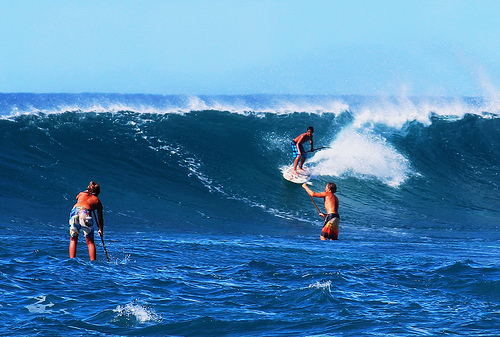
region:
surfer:
[266, 107, 323, 182]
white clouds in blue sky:
[8, 39, 47, 85]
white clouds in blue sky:
[41, 7, 99, 71]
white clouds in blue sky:
[214, 21, 276, 78]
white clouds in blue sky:
[316, 21, 348, 51]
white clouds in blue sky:
[107, 53, 174, 99]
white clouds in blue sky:
[149, 14, 197, 60]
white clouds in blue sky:
[349, 12, 390, 87]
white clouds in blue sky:
[103, 9, 151, 53]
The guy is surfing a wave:
[282, 128, 320, 188]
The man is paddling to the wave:
[69, 178, 115, 265]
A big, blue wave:
[2, 102, 499, 227]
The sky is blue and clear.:
[1, 0, 497, 96]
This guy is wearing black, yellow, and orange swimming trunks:
[303, 178, 340, 250]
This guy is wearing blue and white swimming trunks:
[65, 178, 118, 269]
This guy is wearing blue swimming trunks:
[287, 123, 324, 181]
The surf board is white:
[280, 165, 313, 185]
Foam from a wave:
[3, 69, 499, 159]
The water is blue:
[1, 91, 494, 333]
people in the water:
[12, 113, 401, 277]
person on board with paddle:
[57, 171, 155, 278]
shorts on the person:
[63, 205, 96, 240]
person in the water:
[303, 180, 345, 233]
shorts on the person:
[317, 212, 343, 247]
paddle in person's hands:
[303, 186, 326, 222]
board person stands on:
[285, 162, 311, 185]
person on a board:
[280, 123, 331, 188]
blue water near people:
[23, 243, 479, 323]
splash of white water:
[338, 130, 392, 174]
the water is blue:
[132, 142, 203, 222]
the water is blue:
[133, 138, 239, 246]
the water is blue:
[147, 243, 279, 299]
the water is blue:
[162, 250, 319, 333]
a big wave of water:
[145, 92, 440, 254]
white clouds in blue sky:
[28, 19, 120, 119]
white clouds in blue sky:
[123, 35, 169, 61]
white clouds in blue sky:
[37, 28, 90, 86]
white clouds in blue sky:
[126, 25, 161, 55]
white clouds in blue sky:
[280, 12, 380, 95]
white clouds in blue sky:
[376, 35, 445, 76]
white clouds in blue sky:
[171, 30, 246, 83]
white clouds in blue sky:
[174, 5, 222, 67]